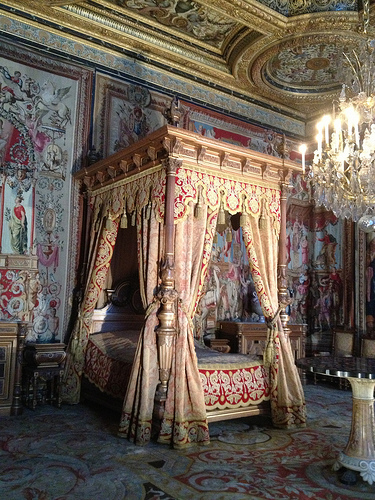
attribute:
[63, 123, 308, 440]
bed — canopy, ornate, red, queen sized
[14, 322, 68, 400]
table — brown, dark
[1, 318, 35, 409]
desk — brown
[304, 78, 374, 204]
chandelier — hanging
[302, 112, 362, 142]
lights — on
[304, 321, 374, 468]
table — glass, marble, black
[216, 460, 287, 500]
carpet — designed, print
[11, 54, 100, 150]
wall — beautiful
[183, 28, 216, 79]
trim — gold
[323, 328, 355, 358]
cushions — black